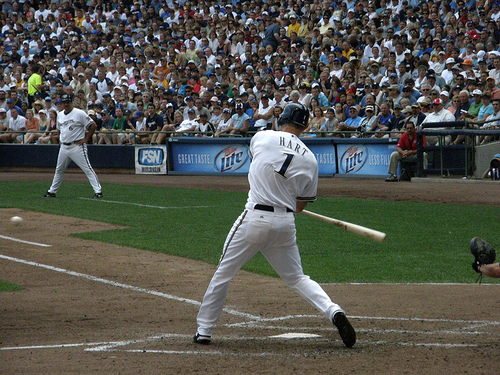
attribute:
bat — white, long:
[297, 205, 389, 242]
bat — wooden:
[297, 212, 387, 240]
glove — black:
[469, 236, 495, 270]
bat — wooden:
[299, 206, 385, 241]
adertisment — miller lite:
[163, 140, 402, 178]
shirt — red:
[395, 131, 435, 155]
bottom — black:
[331, 311, 363, 353]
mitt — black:
[469, 236, 494, 271]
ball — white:
[7, 213, 24, 230]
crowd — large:
[2, 1, 499, 143]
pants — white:
[195, 202, 345, 334]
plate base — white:
[264, 324, 323, 348]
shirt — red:
[395, 131, 425, 151]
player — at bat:
[191, 103, 358, 350]